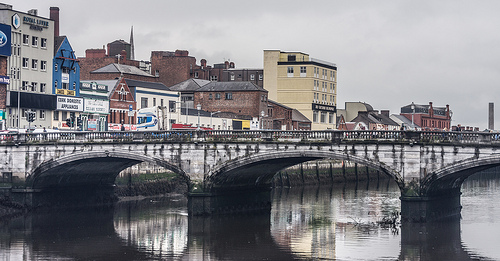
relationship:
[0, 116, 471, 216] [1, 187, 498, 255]
bridge spanning river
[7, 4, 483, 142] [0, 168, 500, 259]
city has reflection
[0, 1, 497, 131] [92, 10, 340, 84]
sky has cloud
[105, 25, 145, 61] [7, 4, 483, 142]
building in city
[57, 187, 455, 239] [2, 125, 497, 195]
reflection of bridge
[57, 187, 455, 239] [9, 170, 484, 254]
reflection on water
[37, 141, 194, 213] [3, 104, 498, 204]
arch on bridge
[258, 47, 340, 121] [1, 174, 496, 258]
yellow building in front of river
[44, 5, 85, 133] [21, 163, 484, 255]
building in front of river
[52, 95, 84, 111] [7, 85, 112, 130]
sign in front of building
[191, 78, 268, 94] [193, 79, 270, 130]
roof on building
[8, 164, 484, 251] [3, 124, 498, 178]
water under bridge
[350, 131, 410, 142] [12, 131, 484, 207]
cars on bridge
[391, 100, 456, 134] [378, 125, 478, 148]
house on hill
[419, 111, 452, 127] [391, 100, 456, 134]
windows on house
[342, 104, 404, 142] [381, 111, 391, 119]
house has chimney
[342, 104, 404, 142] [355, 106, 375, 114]
house has chimney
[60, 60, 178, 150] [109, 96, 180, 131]
two signs on poles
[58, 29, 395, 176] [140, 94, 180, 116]
building with windows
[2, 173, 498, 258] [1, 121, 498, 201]
water under bridge